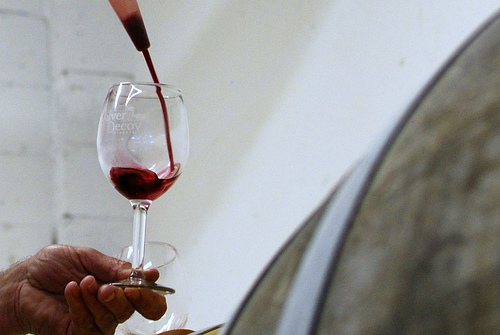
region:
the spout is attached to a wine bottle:
[107, 1, 155, 53]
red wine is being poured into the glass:
[134, 46, 176, 172]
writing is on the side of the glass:
[93, 100, 168, 155]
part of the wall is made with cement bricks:
[4, 5, 164, 333]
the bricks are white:
[3, 3, 151, 294]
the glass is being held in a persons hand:
[4, 238, 167, 333]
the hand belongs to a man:
[2, 240, 168, 333]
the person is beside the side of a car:
[224, 7, 499, 334]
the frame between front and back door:
[281, 117, 401, 327]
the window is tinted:
[323, 19, 496, 329]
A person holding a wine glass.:
[88, 72, 196, 295]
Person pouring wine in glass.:
[97, 7, 189, 194]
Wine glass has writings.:
[107, 107, 149, 142]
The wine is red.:
[110, 167, 174, 183]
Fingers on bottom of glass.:
[81, 245, 191, 318]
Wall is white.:
[178, 18, 330, 157]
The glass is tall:
[76, 75, 208, 296]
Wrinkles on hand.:
[37, 243, 92, 281]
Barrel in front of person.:
[301, 103, 478, 286]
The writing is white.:
[103, 111, 155, 146]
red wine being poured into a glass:
[81, 0, 198, 303]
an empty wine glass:
[110, 235, 194, 330]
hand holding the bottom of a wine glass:
[5, 228, 175, 328]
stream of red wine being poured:
[135, 46, 185, 176]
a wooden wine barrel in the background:
[226, 5, 493, 330]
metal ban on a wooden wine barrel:
[275, 155, 369, 330]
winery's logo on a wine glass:
[97, 98, 155, 153]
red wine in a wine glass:
[102, 154, 182, 210]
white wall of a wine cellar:
[244, 34, 348, 149]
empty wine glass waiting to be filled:
[104, 233, 204, 334]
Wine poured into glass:
[86, 63, 196, 217]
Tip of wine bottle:
[106, 5, 167, 65]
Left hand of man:
[18, 233, 180, 333]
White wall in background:
[187, 10, 382, 144]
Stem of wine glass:
[123, 213, 161, 288]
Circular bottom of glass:
[105, 270, 179, 298]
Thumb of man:
[118, 253, 158, 284]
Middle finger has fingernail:
[96, 286, 116, 301]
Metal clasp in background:
[277, 147, 383, 332]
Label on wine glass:
[98, 103, 155, 135]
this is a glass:
[97, 77, 189, 190]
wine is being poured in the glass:
[97, 29, 188, 200]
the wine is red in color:
[119, 172, 162, 192]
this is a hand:
[11, 248, 118, 326]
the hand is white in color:
[37, 252, 76, 277]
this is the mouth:
[121, 14, 158, 54]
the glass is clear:
[113, 82, 151, 125]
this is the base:
[112, 269, 174, 291]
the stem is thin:
[123, 201, 154, 256]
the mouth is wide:
[116, 79, 180, 98]